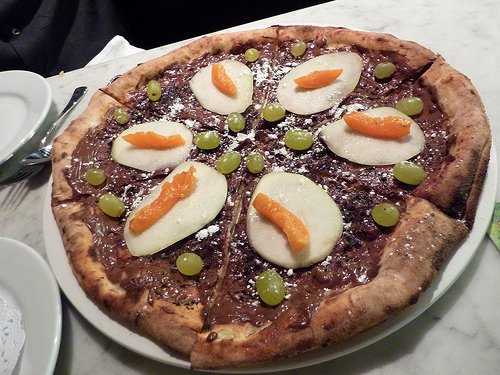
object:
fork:
[0, 84, 88, 185]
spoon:
[19, 74, 122, 168]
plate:
[1, 237, 64, 375]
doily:
[1, 301, 27, 374]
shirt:
[1, 0, 141, 78]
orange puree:
[251, 191, 309, 251]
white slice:
[247, 168, 342, 268]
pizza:
[50, 23, 492, 368]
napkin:
[81, 32, 142, 69]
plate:
[0, 68, 52, 166]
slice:
[247, 21, 458, 170]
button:
[10, 28, 23, 35]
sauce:
[69, 39, 457, 330]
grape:
[371, 59, 397, 79]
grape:
[394, 94, 425, 116]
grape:
[390, 158, 427, 183]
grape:
[254, 269, 283, 304]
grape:
[369, 201, 401, 227]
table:
[1, 0, 496, 375]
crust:
[48, 25, 494, 368]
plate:
[43, 26, 497, 373]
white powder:
[248, 55, 296, 89]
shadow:
[0, 175, 31, 216]